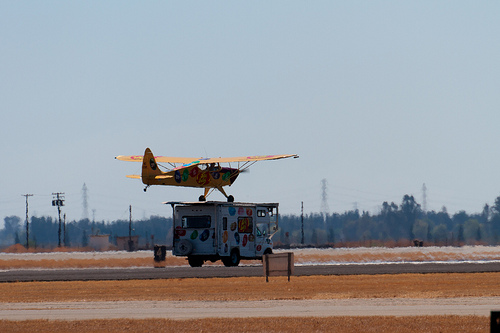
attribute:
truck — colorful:
[164, 195, 287, 265]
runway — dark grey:
[0, 261, 499, 282]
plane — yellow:
[125, 145, 298, 207]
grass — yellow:
[1, 272, 498, 304]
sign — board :
[261, 247, 296, 284]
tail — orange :
[123, 146, 175, 191]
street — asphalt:
[1, 262, 496, 284]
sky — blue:
[80, 43, 388, 145]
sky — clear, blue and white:
[3, 4, 498, 205]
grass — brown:
[0, 320, 492, 329]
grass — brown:
[4, 276, 496, 295]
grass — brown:
[1, 257, 180, 265]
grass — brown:
[301, 254, 498, 259]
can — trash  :
[151, 243, 171, 271]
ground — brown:
[159, 281, 240, 305]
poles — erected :
[49, 193, 71, 248]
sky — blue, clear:
[3, 12, 490, 144]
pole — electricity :
[20, 191, 32, 247]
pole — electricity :
[51, 189, 63, 245]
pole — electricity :
[128, 203, 135, 238]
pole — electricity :
[298, 200, 307, 245]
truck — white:
[171, 201, 305, 266]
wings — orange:
[119, 133, 299, 180]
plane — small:
[105, 146, 305, 200]